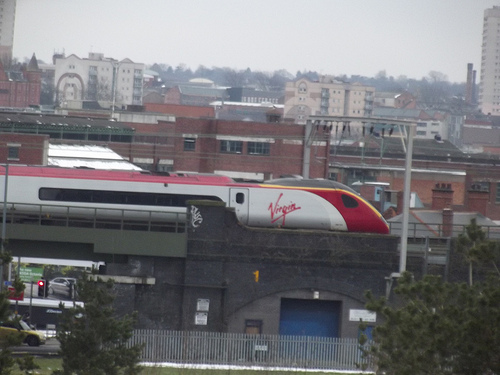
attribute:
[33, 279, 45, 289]
light — red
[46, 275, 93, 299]
car — silver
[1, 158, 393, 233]
train — white, red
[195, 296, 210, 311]
sign — white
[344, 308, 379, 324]
sign — white, rectangular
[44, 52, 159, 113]
building — white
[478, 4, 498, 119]
building — tall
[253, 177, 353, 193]
stripe — yellow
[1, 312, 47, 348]
car — yellow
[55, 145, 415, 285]
train — passenger, red, white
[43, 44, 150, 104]
building — maroon, white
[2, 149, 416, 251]
train — long, white, red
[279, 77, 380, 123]
building — tan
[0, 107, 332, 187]
building — red, brick, large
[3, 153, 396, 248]
train — subway, silver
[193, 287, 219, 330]
signs — white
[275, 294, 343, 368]
doors — blue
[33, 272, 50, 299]
traffic light — red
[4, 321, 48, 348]
car — small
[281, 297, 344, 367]
doors — blue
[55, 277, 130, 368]
tree — green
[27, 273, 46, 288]
signal — traffic, red